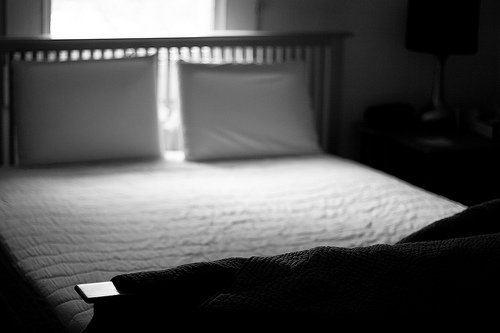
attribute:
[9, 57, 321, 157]
pillows — white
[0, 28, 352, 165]
headboard — wooden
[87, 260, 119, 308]
footboard — wooden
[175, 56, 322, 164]
pillow — white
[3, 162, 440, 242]
comforter — white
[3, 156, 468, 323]
sheet — white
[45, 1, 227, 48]
window — sunlit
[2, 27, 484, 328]
bed — sunlit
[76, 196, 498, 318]
blanket — draped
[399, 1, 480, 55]
shade — square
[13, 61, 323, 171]
pillows — leaning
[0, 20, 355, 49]
slat — wooden